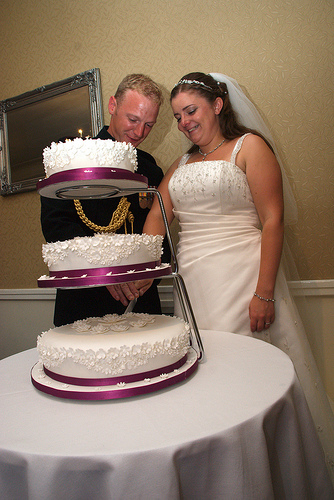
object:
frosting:
[41, 135, 139, 176]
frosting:
[37, 231, 170, 280]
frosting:
[35, 310, 191, 379]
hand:
[247, 294, 277, 334]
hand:
[130, 277, 154, 296]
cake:
[31, 130, 198, 399]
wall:
[0, 0, 334, 500]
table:
[166, 398, 212, 428]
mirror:
[0, 66, 113, 195]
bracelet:
[247, 284, 287, 309]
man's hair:
[114, 72, 164, 106]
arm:
[244, 153, 289, 304]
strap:
[224, 131, 257, 166]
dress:
[167, 131, 333, 493]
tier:
[37, 130, 151, 203]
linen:
[0, 325, 331, 498]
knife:
[121, 292, 141, 315]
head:
[108, 72, 163, 148]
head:
[170, 72, 225, 149]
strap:
[177, 145, 189, 168]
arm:
[142, 158, 184, 241]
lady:
[130, 69, 285, 500]